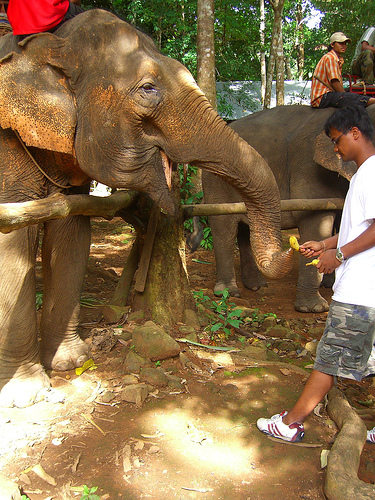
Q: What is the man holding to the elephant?
A: Food.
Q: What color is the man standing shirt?
A: White.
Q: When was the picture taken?
A: Daytime.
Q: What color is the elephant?
A: Brown.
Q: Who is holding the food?
A: Man in white shirt.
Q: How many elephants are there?
A: Two.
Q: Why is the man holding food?
A: To feed the elephant.